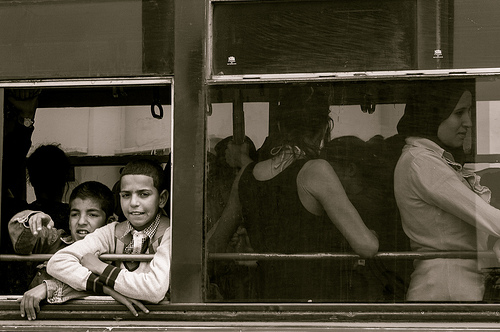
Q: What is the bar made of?
A: Metal.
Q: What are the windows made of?
A: Glass.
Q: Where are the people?
A: On a bus.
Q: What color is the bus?
A: Black.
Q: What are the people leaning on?
A: A bar.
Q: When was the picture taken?
A: Daytime.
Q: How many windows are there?
A: Two.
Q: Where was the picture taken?
A: On a bus or train.